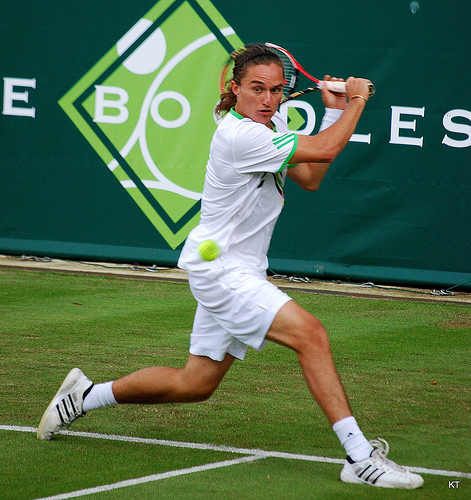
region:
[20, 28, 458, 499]
Tennis player hitting a ball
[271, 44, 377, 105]
Tennis racket is red and white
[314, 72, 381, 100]
Handle of racket is white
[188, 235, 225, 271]
Ball is green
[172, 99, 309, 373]
White outfit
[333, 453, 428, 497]
Shoe is white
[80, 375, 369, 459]
Socks are white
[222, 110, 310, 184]
Sleeve has green border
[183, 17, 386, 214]
Player holds racket with both hands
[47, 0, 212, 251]
Green diamond shape behind player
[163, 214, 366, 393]
the man is hitting a ball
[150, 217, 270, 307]
the ball is green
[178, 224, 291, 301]
the ball is in the air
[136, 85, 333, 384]
the man's clothes are white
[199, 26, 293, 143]
the man's hair is in a pony tail.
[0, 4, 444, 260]
the wall is dark green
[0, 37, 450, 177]
the wall has white letters on it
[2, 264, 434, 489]
the tennis court is made of green grass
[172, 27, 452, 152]
the man is holding a tennis racket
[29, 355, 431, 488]
the man's shoes have stripes on them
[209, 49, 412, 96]
Tennis racquet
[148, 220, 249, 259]
a tennis ball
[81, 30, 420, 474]
a tennis player swinging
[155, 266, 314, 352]
white shorts on a man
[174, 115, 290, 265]
a white shirt with green stripes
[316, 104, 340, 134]
a wristband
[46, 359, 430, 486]
tennis shoes on a tennis player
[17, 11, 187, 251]
an advertisement banner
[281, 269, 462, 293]
chains holding a banner in place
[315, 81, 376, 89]
tape on the base of a tennis racquet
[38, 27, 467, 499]
a tennis player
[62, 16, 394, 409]
a tennis player hitting a ball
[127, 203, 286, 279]
a tennis ball in the air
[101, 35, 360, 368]
a tennis player wearing white and green outfit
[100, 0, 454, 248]
tennis player holding racket in air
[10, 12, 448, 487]
tennis player swing at ball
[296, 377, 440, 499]
white and black shoes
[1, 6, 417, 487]
tennis player playing on grass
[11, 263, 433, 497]
a grassy tennis court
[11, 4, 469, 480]
tennis player in stance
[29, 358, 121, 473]
White shoe with black lines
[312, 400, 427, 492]
White sock on a man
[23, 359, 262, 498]
Green field with white lines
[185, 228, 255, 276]
Green ball in the air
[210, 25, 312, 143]
Man's face who is playing tennis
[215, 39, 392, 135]
Tennis racquet in a hand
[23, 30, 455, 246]
Green and white sign on a field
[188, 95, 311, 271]
White shirt with green stripes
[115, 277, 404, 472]
Legs on a man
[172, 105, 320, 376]
White outfit on a man